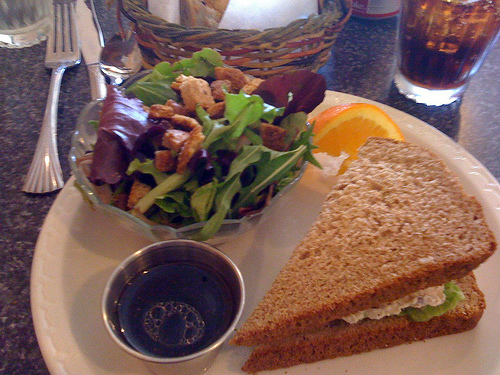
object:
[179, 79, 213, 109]
crouton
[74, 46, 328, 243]
salad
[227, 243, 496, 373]
crust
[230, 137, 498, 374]
bread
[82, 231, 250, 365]
cup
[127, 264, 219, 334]
dressing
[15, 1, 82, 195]
fork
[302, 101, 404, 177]
orange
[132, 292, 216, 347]
bubbles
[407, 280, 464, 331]
lettuce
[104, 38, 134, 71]
silver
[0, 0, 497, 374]
table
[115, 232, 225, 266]
holder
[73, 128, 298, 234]
bowl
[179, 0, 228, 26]
bread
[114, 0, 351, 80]
basket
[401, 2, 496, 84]
cola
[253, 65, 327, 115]
leaf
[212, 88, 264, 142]
leaf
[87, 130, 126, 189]
leaf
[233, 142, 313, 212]
leaf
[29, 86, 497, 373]
plate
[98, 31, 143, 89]
spoon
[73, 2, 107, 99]
knife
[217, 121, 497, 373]
triangle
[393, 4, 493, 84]
beverage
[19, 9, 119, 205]
set